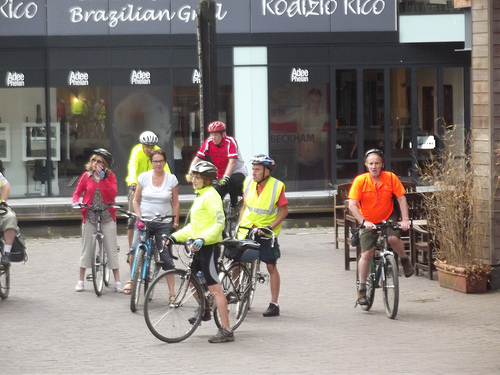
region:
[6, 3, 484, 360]
cyclists in a shopping area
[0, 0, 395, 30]
names of various businesses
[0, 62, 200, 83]
repeated name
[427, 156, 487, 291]
potted brown vegetation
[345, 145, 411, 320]
rider in an orange shirt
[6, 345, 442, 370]
paved surface of the outdoor area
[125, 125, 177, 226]
rider with a helmet and rider without a helmet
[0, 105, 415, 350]
group of eight on their bicycles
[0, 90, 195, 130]
inside the store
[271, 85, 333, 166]
image of a man inside the store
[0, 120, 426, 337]
Group of people of bikes.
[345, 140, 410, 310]
Man in orange shirt.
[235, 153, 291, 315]
Man in neon safety jacket and orange t-shirt.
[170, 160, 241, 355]
Woman in bright yellow shirt.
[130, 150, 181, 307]
Woman in white t-shirt.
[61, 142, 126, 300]
Woman wearing red sweater.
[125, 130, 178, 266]
Man in bright yellow jacket with white stripe.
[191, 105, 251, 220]
Man wearing red shirt.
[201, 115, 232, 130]
Red helmet worn by man on bike.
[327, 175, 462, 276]
Wooden chairs on the side.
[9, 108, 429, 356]
person riding bikes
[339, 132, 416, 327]
man wearing orange top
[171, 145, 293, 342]
people wearing green tops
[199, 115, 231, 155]
a red helmet on head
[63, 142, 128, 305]
woman stands on a bike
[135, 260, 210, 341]
front wheel of bike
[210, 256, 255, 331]
back wheel of bike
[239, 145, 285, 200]
man wearing a helmet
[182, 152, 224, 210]
woman wearing a helmet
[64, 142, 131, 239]
woman wears red top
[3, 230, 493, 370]
riders and bicycles on gray ground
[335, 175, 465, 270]
dark wooden table and chairs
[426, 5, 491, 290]
tall tan plants by tiled wall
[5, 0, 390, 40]
gray awning with white lettering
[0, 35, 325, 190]
large windows on storefront with displays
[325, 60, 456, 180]
panels of glass with furniture inside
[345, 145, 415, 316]
rider in orange shirt riding bicycle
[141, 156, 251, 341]
biker standing over angled bike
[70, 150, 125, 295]
woman scratching face while standing over bicycle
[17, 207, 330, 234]
canal of gray water behind people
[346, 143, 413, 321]
man in orange shirt riding a bike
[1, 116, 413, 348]
group of bikers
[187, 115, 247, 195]
biker with red shirt and helmet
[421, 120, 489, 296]
dead plant in front of building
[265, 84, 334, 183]
advertising poster showing David Beckham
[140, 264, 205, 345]
front tire of nearest bike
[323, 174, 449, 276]
wooden chairs behind a biker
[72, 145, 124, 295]
woman in red sweater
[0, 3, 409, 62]
sign on top of storefront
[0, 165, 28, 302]
person on bike half out of frame